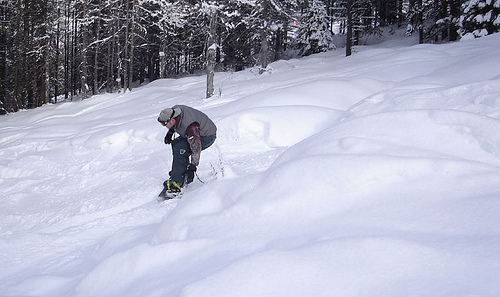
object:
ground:
[0, 21, 500, 297]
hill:
[1, 23, 498, 295]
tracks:
[40, 196, 153, 236]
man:
[157, 104, 216, 187]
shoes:
[163, 180, 186, 188]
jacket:
[172, 104, 217, 138]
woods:
[0, 0, 500, 116]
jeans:
[169, 135, 216, 183]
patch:
[180, 149, 186, 154]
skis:
[159, 173, 189, 198]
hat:
[159, 108, 181, 122]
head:
[160, 109, 176, 129]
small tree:
[0, 0, 500, 115]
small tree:
[0, 0, 500, 134]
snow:
[0, 0, 500, 295]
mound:
[269, 114, 385, 191]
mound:
[227, 104, 329, 134]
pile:
[206, 105, 341, 152]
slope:
[0, 36, 499, 297]